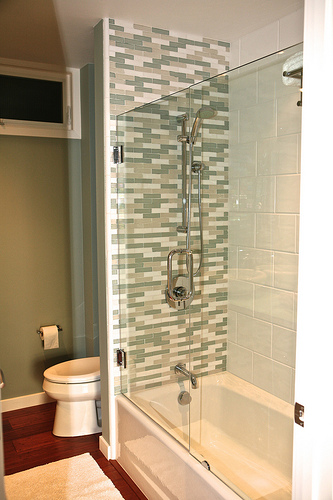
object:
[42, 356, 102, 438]
toilet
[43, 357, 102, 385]
seat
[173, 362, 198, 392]
faucet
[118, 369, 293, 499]
bathtub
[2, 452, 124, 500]
rug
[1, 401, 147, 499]
floor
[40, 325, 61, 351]
toilet paper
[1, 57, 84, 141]
window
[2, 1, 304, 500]
bathroom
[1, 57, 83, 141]
frame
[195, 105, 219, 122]
shower head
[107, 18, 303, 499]
shower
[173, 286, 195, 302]
hot and cold knob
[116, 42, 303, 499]
shower door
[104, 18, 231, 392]
tile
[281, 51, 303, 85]
towel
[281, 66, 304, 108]
rack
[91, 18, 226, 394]
wall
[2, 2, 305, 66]
ceiling